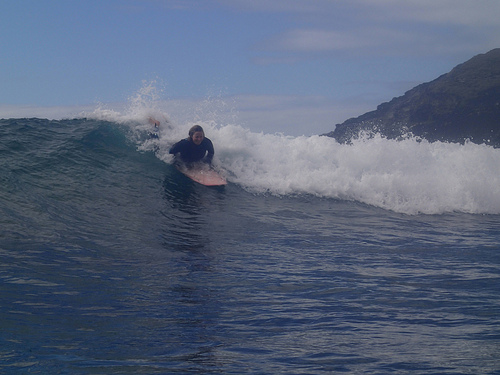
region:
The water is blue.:
[65, 260, 365, 369]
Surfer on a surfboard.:
[149, 120, 237, 194]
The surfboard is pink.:
[181, 165, 239, 192]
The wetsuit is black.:
[163, 125, 218, 167]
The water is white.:
[231, 135, 499, 219]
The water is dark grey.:
[366, 39, 497, 168]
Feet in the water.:
[137, 105, 177, 131]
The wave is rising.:
[338, 62, 498, 164]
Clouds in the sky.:
[170, 91, 339, 130]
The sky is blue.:
[5, 7, 220, 87]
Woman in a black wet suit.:
[165, 125, 217, 167]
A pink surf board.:
[188, 161, 232, 185]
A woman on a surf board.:
[148, 116, 229, 186]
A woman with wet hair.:
[136, 113, 216, 165]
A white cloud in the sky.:
[255, 27, 441, 69]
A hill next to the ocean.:
[314, 30, 499, 152]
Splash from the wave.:
[119, 72, 171, 117]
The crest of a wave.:
[82, 76, 499, 214]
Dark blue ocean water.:
[0, 116, 498, 373]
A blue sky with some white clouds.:
[2, 2, 499, 135]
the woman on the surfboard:
[147, 121, 231, 191]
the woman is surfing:
[134, 100, 229, 191]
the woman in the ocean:
[133, 110, 246, 200]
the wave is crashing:
[240, 127, 489, 214]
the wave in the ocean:
[222, 124, 484, 216]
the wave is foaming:
[236, 118, 493, 229]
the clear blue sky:
[7, 3, 149, 59]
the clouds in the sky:
[283, 15, 420, 68]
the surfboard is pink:
[174, 166, 227, 188]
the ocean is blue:
[26, 224, 309, 340]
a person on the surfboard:
[128, 95, 237, 203]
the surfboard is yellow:
[176, 155, 231, 195]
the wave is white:
[57, 100, 496, 250]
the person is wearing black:
[164, 120, 223, 171]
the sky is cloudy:
[1, 1, 499, 141]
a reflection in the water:
[139, 159, 239, 374]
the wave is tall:
[323, 41, 497, 173]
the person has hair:
[165, 117, 217, 169]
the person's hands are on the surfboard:
[166, 120, 228, 190]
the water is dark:
[0, 45, 499, 372]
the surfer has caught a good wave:
[17, 2, 492, 365]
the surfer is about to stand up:
[160, 117, 229, 201]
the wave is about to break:
[117, 105, 495, 219]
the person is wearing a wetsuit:
[163, 122, 220, 167]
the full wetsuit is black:
[167, 134, 217, 163]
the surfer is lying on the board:
[161, 125, 230, 190]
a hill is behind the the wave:
[307, 40, 493, 171]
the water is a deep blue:
[2, 112, 492, 362]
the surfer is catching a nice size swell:
[58, 111, 383, 367]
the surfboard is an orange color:
[182, 162, 229, 188]